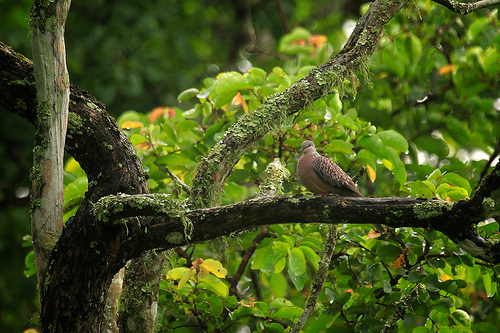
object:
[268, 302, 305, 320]
leaf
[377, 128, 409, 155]
leaf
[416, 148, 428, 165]
gap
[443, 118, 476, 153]
leaves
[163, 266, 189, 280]
leaf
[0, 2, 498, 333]
tree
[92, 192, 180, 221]
nest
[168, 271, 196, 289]
leaf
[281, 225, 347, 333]
branches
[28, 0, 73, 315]
tree trunk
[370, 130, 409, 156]
leaf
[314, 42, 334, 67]
leaf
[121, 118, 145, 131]
oranges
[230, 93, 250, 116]
yellow leaves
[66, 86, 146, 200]
trunk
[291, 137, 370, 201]
bird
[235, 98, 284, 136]
moss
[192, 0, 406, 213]
branch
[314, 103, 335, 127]
drop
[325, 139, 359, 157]
leaf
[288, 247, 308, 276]
leaf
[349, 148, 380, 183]
leaf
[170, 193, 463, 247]
branch